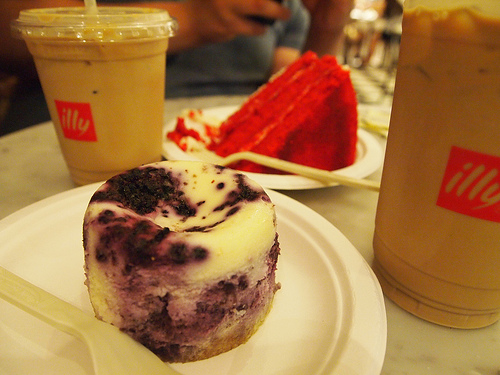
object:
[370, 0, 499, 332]
coffee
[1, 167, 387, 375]
plate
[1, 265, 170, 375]
fork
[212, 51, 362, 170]
cake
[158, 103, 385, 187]
plate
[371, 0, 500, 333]
cup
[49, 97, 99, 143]
logo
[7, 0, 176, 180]
cup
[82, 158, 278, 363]
cake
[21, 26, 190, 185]
coffee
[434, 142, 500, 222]
square logo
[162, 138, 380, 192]
fork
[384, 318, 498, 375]
table